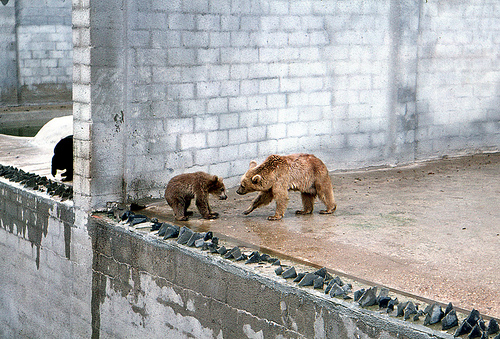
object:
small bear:
[163, 170, 231, 223]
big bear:
[233, 152, 336, 220]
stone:
[281, 265, 297, 281]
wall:
[68, 0, 500, 215]